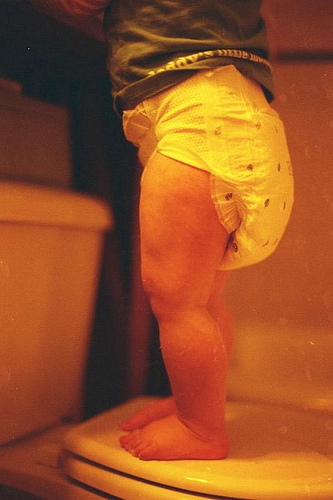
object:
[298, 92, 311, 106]
sky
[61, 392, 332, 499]
lid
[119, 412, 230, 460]
baby's foot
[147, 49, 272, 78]
writing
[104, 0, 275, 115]
tshirt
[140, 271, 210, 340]
knee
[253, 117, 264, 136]
pattern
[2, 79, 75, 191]
tissue box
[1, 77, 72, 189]
blurry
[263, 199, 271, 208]
pattern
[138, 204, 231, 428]
legs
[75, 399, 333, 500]
board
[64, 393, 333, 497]
toilet seat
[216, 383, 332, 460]
shadow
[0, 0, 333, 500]
toilet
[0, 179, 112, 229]
lid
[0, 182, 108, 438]
tank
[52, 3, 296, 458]
baby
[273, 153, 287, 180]
pattern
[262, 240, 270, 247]
pattern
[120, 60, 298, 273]
diaper